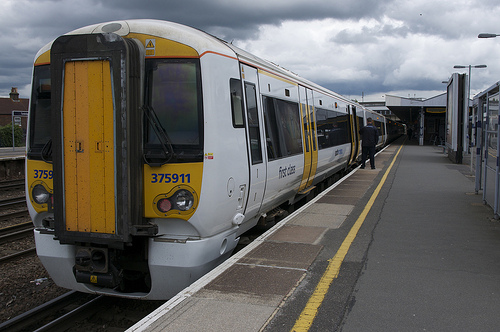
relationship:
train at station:
[25, 16, 402, 303] [137, 30, 491, 330]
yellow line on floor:
[290, 193, 375, 330] [307, 204, 496, 328]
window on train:
[258, 93, 327, 162] [17, 7, 406, 330]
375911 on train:
[148, 168, 191, 185] [17, 7, 406, 330]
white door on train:
[237, 60, 272, 230] [14, 9, 354, 320]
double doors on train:
[300, 88, 317, 193] [25, 16, 402, 303]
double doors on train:
[346, 102, 357, 164] [25, 16, 402, 303]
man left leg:
[359, 115, 382, 168] [358, 139, 369, 170]